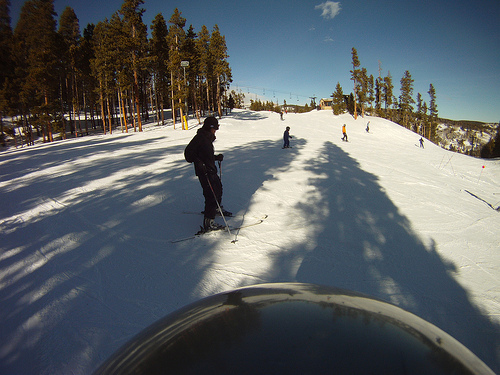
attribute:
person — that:
[186, 117, 227, 231]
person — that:
[281, 126, 295, 152]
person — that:
[339, 116, 348, 143]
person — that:
[416, 132, 424, 148]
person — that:
[273, 108, 285, 122]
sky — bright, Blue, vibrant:
[38, 0, 498, 127]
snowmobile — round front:
[72, 281, 495, 371]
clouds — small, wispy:
[291, 1, 411, 36]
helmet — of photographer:
[92, 283, 493, 368]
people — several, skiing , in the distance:
[181, 106, 426, 233]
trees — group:
[1, 4, 240, 125]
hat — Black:
[201, 115, 218, 125]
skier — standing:
[166, 111, 269, 248]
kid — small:
[282, 127, 297, 152]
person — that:
[276, 121, 301, 163]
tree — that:
[119, 3, 152, 130]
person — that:
[183, 119, 235, 234]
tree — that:
[91, 37, 116, 137]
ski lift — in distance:
[145, 53, 321, 115]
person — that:
[341, 122, 348, 142]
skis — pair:
[169, 207, 267, 244]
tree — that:
[56, 13, 88, 144]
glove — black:
[216, 151, 225, 163]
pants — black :
[195, 170, 225, 217]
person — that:
[411, 135, 430, 153]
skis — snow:
[362, 130, 374, 135]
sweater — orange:
[341, 124, 348, 137]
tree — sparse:
[424, 83, 441, 144]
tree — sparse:
[398, 66, 414, 125]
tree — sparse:
[376, 65, 397, 115]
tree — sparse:
[345, 44, 370, 112]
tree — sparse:
[331, 83, 347, 113]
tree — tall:
[10, 7, 243, 131]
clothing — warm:
[174, 109, 257, 249]